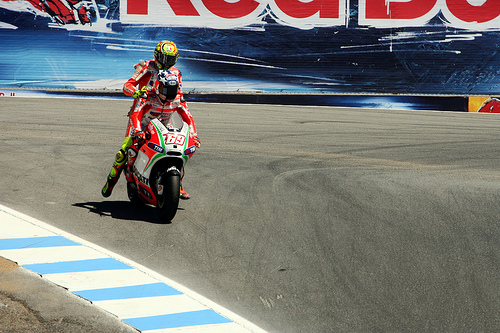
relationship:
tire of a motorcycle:
[147, 167, 184, 222] [118, 109, 194, 221]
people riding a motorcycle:
[118, 36, 199, 135] [118, 109, 194, 221]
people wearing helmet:
[125, 70, 202, 200] [152, 39, 179, 68]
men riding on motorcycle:
[118, 36, 199, 135] [118, 109, 194, 221]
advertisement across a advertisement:
[109, 0, 499, 42] [0, 0, 499, 115]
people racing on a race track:
[118, 36, 199, 135] [3, 76, 500, 330]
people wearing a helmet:
[125, 70, 202, 200] [152, 39, 179, 68]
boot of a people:
[95, 160, 128, 198] [125, 70, 202, 200]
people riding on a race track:
[118, 36, 199, 135] [3, 76, 500, 330]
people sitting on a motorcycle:
[118, 36, 199, 135] [118, 109, 194, 221]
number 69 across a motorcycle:
[161, 129, 190, 149] [118, 109, 194, 221]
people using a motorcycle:
[118, 36, 199, 135] [118, 109, 194, 221]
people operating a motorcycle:
[118, 36, 199, 135] [118, 109, 194, 221]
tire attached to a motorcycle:
[147, 167, 184, 222] [118, 109, 194, 221]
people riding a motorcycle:
[125, 70, 202, 200] [118, 109, 194, 221]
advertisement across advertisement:
[109, 0, 499, 42] [0, 0, 499, 115]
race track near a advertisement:
[3, 76, 500, 330] [109, 0, 499, 42]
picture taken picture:
[102, 40, 201, 220] [0, 0, 500, 333]